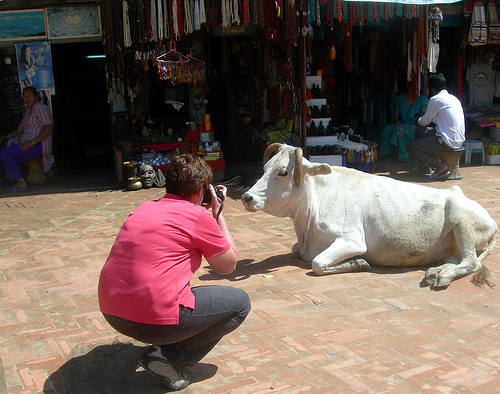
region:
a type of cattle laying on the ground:
[243, 146, 496, 287]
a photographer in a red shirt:
[104, 154, 249, 391]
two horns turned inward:
[260, 141, 303, 185]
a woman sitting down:
[6, 82, 57, 189]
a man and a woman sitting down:
[378, 74, 462, 176]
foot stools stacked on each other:
[465, 137, 486, 170]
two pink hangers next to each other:
[153, 39, 205, 69]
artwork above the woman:
[2, 7, 102, 92]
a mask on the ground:
[134, 165, 157, 187]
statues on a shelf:
[297, 80, 340, 161]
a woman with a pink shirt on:
[78, 193, 287, 339]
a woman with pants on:
[102, 272, 317, 374]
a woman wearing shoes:
[128, 310, 256, 385]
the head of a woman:
[163, 133, 238, 212]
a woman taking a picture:
[112, 140, 274, 260]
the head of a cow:
[235, 123, 336, 238]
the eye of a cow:
[261, 163, 303, 195]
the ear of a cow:
[292, 158, 334, 190]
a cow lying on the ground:
[234, 123, 495, 295]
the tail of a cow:
[465, 202, 495, 297]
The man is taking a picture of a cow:
[77, 115, 498, 383]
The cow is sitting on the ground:
[239, 132, 491, 307]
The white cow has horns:
[236, 129, 493, 295]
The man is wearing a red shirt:
[85, 183, 246, 325]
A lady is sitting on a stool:
[3, 74, 55, 200]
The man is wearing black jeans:
[95, 278, 257, 362]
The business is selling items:
[105, 13, 485, 176]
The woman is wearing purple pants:
[4, 136, 54, 179]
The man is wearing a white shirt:
[413, 88, 470, 150]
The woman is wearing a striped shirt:
[16, 101, 53, 157]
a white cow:
[242, 143, 492, 295]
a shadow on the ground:
[47, 362, 119, 391]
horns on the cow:
[294, 148, 308, 180]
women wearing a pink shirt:
[122, 222, 174, 287]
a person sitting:
[8, 88, 59, 152]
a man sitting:
[415, 75, 466, 150]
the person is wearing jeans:
[196, 288, 252, 314]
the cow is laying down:
[239, 144, 493, 285]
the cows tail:
[475, 248, 499, 269]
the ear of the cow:
[308, 161, 335, 179]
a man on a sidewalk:
[21, 89, 486, 364]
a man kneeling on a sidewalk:
[61, 144, 285, 386]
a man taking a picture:
[83, 98, 390, 389]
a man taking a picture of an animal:
[94, 123, 430, 382]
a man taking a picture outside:
[94, 148, 446, 392]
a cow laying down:
[186, 88, 498, 354]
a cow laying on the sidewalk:
[219, 111, 485, 351]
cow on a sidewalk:
[157, 87, 493, 365]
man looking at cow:
[122, 73, 492, 344]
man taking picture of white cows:
[116, 111, 451, 389]